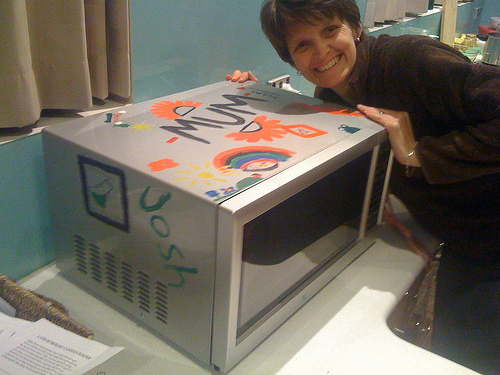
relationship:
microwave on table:
[38, 78, 393, 373] [21, 273, 440, 368]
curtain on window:
[3, 0, 149, 127] [0, 0, 148, 135]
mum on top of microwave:
[160, 92, 266, 143] [38, 78, 393, 373]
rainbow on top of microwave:
[212, 145, 297, 173] [38, 78, 393, 373]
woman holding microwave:
[255, 0, 500, 374] [38, 78, 393, 373]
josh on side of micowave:
[138, 186, 199, 287] [49, 77, 402, 371]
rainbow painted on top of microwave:
[208, 142, 296, 172] [32, 95, 404, 365]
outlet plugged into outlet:
[268, 74, 293, 89] [267, 73, 295, 93]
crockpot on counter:
[481, 32, 498, 64] [38, 264, 433, 367]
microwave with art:
[38, 78, 393, 373] [159, 92, 254, 142]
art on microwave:
[138, 172, 196, 284] [38, 78, 393, 373]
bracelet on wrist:
[403, 145, 423, 177] [394, 131, 432, 172]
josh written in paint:
[128, 172, 213, 299] [135, 185, 164, 223]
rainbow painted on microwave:
[212, 145, 297, 173] [58, 76, 389, 348]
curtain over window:
[0, 0, 150, 127] [5, 5, 140, 145]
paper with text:
[1, 325, 103, 374] [20, 344, 67, 367]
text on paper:
[20, 344, 67, 367] [1, 325, 103, 374]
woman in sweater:
[255, 0, 497, 220] [385, 38, 491, 148]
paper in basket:
[1, 317, 124, 374] [0, 269, 94, 374]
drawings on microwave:
[213, 106, 326, 196] [38, 78, 393, 373]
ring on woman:
[377, 109, 389, 124] [255, 0, 500, 374]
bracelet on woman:
[405, 144, 416, 177] [256, 1, 483, 248]